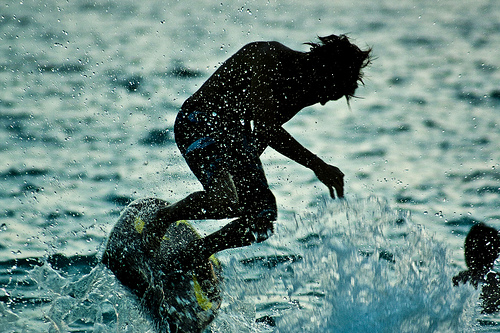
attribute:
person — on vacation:
[129, 22, 405, 225]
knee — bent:
[202, 182, 239, 217]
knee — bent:
[242, 205, 277, 240]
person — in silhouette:
[441, 200, 496, 317]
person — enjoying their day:
[159, 14, 369, 279]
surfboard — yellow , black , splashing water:
[103, 197, 223, 331]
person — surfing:
[156, 31, 371, 263]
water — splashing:
[308, 197, 450, 330]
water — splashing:
[303, 208, 440, 320]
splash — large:
[290, 195, 487, 331]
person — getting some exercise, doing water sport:
[137, 26, 381, 281]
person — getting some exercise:
[447, 215, 499, 330]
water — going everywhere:
[284, 164, 469, 296]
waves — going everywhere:
[61, 83, 475, 255]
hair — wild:
[307, 30, 372, 102]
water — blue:
[396, 4, 430, 75]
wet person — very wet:
[75, 23, 380, 331]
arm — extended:
[271, 128, 325, 177]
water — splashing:
[300, 216, 440, 313]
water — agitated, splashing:
[2, 4, 494, 328]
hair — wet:
[315, 25, 367, 82]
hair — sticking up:
[309, 33, 375, 106]